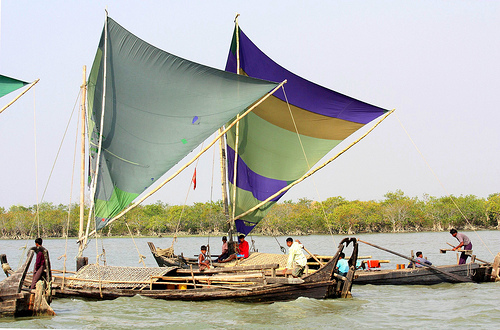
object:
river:
[364, 287, 459, 329]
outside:
[3, 6, 494, 328]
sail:
[214, 16, 400, 264]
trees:
[428, 193, 496, 231]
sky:
[3, 5, 498, 202]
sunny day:
[5, 3, 498, 328]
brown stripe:
[231, 87, 365, 140]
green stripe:
[207, 108, 343, 180]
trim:
[227, 20, 387, 124]